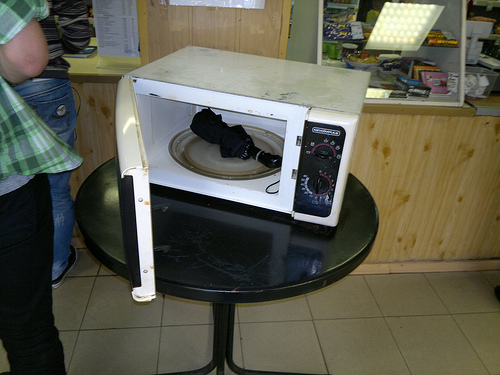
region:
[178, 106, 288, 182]
Umbrella in a microwave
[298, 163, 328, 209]
Dial on a microwave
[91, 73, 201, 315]
Door to a microwave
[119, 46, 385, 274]
Microwave on a table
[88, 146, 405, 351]
Black table in a room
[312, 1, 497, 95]
Glass display case on a counter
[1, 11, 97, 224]
Plaid shirt on a person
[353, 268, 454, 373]
Tile on a floor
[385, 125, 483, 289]
Tan wood wall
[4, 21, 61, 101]
Elbow on a person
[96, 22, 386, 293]
The microwave is sitting on a table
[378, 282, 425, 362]
The floor has tile on it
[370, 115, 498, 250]
Wooden paneling on counter front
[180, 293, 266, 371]
Base of the table underneath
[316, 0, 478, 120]
The cabinet is full of food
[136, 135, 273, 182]
Inside of microwave is dirty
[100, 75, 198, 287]
Door of microwave is open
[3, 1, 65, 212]
The person's shirt is plaid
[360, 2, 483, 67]
Reflection of light on door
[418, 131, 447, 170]
Knot in the wood panel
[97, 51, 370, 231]
an old microwave with an umbrella in it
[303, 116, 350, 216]
dials on a microwave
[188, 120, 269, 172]
an umbrella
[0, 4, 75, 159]
a person's arm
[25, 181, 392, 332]
a round table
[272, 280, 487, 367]
a section of tile floor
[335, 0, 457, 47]
light reflection on glass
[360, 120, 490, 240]
a wooden counter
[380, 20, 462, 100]
a snack display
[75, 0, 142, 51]
a snack menu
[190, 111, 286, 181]
A black umbrella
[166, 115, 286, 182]
A glass microwave tray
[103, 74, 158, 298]
A white microwave door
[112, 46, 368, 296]
an old white microwave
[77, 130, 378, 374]
A black wooden table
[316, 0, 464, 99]
A glass display case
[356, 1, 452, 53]
reflection of lights on the display case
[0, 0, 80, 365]
A person in a green shirt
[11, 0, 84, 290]
A person in a grey striped shirt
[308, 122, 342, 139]
branding on the microwave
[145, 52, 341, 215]
this is an oven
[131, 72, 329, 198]
the microwave is open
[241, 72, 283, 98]
the microwave is white in color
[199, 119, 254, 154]
this is an umbrella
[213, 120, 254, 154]
the umbrella is black in color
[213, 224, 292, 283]
this is a table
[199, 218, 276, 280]
the table is black in color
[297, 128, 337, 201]
the buttons are black in color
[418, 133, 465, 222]
the board is wooden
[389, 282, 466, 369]
the floor is tiled